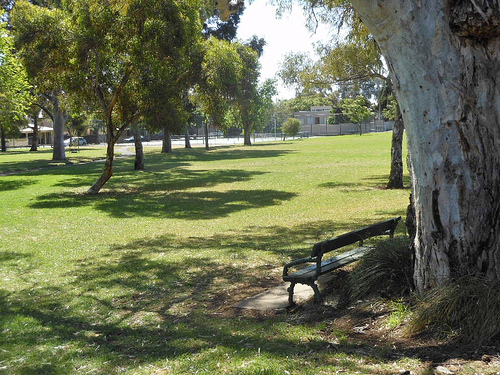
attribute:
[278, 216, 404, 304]
bench — wood, wrought, iron, wooden, fixed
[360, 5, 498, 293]
bark — white, behind, thick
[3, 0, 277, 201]
trees — growing, row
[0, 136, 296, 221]
shadows — cast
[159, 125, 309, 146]
court — tennis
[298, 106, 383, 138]
building — office, white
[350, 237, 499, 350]
grass — wild, long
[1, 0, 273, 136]
leaves — green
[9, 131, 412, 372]
grass — green, great, cut, short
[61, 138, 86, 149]
car — silver, parked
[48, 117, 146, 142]
building — brown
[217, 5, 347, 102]
sky — white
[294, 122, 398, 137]
fence — distant, linked, chain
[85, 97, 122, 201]
trunk — bent, thin